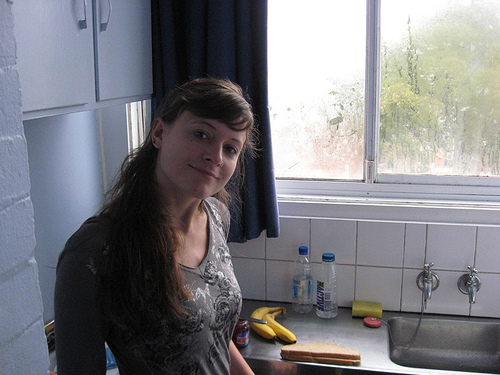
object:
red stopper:
[363, 316, 381, 327]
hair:
[128, 164, 173, 279]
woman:
[54, 75, 256, 375]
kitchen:
[0, 4, 496, 369]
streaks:
[394, 6, 500, 177]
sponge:
[351, 301, 384, 317]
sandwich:
[280, 341, 361, 367]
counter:
[234, 281, 497, 373]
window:
[266, 5, 498, 185]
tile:
[354, 221, 407, 268]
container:
[231, 320, 251, 349]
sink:
[385, 316, 497, 371]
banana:
[263, 310, 298, 343]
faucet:
[416, 261, 440, 299]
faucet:
[458, 265, 483, 305]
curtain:
[149, 0, 280, 244]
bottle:
[315, 253, 338, 319]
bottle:
[292, 246, 315, 314]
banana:
[248, 306, 278, 340]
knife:
[239, 317, 268, 324]